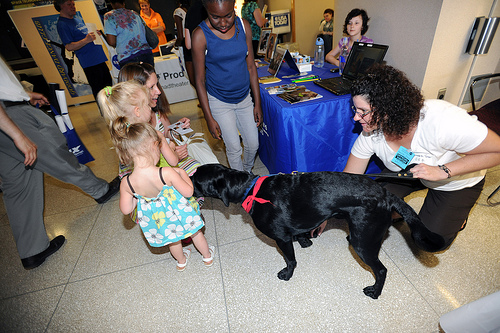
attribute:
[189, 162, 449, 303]
dog — black lab, black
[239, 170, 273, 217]
tie — red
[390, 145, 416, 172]
tag — blue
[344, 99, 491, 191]
shirt — white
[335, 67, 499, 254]
woman — kneeling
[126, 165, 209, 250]
dress — blue, flowered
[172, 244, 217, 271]
sandals — white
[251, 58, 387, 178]
cloth — blue, royal blue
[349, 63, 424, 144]
hair — black, curly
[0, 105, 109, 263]
pants — grey, black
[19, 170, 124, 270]
shoes — black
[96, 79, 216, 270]
children — girls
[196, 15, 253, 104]
tank top — blue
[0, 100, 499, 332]
floor — grey, tile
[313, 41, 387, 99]
laptop — black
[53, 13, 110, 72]
shirt — blue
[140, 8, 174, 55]
shirt — orange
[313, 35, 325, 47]
top — blue